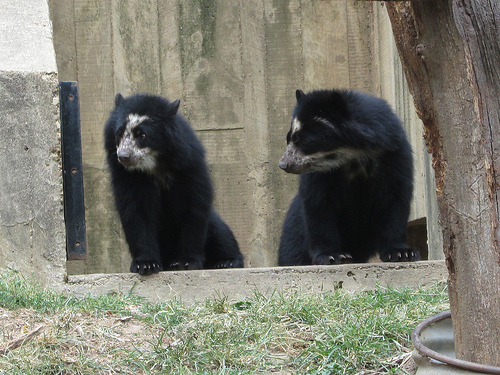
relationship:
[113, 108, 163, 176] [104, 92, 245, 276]
face on animal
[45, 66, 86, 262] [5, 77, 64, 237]
pillar on wall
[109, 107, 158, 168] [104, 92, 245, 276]
patch on animal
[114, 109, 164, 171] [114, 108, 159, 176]
face has hair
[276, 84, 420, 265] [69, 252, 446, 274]
animal stands on ledge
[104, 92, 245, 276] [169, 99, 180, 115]
animal has bear's ear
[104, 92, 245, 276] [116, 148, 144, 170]
animal has nose